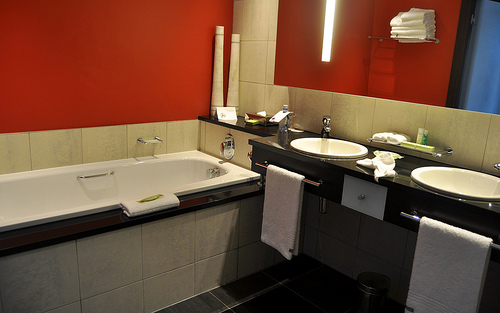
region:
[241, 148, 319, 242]
Towel is hanging off the rack.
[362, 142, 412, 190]
A wash towel on the bathroom counter.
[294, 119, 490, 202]
Two wash bowl in the bathroom.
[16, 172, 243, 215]
A white tub in bathroom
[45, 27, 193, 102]
The wall is red.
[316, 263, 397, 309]
The garbage can under the sink.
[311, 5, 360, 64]
The light is showing in the mirror.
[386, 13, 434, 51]
Towels are on the shelf.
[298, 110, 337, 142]
The faucet is on the sink.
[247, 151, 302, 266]
The towel is white.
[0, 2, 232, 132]
orange bathroom wall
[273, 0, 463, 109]
orange bathroom wall as seen thru the mirror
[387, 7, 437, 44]
stack of towels as seen thru a mirror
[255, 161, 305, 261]
towel on left side of sink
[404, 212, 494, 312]
towel on right side of sink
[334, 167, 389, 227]
drawer in the middle of the sink cabinet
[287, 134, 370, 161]
left sink basin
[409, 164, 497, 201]
right sink basin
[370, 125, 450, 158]
washrags and toiletries on small shelf above sink cabinet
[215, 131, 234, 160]
bathtub faucet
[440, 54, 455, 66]
part of a mirror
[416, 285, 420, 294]
part of a towel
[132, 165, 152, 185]
part of a sink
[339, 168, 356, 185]
top of a table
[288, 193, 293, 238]
edge of a towel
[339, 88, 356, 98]
edge of a mirror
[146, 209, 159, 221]
edge of a sink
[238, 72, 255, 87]
edge of a wall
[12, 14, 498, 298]
this is a large bathroom area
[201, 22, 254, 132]
these are two wall decorations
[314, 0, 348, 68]
this is a light on the wall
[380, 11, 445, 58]
folded towels on a wall rack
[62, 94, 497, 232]
three sinks in the bathroom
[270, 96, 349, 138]
faucets on a sink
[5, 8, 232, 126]
this bathroom has orange walls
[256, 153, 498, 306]
two towels on the racks by the sink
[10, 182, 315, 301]
a grey sink cabinet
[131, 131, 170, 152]
a soap dish on the wall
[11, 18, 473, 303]
bathroom area for a home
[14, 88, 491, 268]
this is a big bathroom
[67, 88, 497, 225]
this bathroom has three sinks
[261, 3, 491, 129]
this is the bathroom mirror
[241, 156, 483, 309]
white towels in the bathroom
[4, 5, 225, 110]
the wall is orange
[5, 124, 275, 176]
tiling on the wall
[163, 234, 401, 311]
the floor is black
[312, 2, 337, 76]
a light on the wall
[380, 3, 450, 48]
folded towels on a shelf